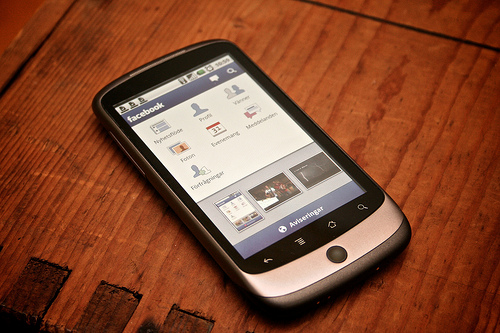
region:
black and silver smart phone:
[87, 30, 412, 317]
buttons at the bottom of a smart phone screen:
[252, 191, 378, 267]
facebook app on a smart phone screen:
[110, 44, 339, 171]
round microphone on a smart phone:
[322, 240, 353, 270]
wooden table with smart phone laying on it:
[10, 3, 492, 325]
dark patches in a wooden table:
[3, 248, 217, 327]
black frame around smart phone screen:
[98, 35, 388, 275]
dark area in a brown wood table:
[12, 0, 116, 99]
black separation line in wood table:
[292, 0, 494, 58]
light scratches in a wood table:
[23, 156, 165, 258]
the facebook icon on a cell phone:
[123, 97, 168, 132]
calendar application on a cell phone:
[204, 115, 239, 155]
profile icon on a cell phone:
[185, 92, 214, 128]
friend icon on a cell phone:
[218, 77, 245, 102]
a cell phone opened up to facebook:
[88, 31, 461, 323]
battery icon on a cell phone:
[193, 67, 214, 80]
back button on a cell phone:
[253, 251, 284, 276]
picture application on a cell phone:
[248, 163, 300, 215]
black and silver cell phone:
[76, 53, 441, 316]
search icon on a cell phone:
[225, 58, 241, 80]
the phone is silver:
[79, 30, 450, 318]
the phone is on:
[92, 5, 420, 295]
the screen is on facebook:
[98, 42, 355, 225]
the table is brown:
[346, 33, 468, 295]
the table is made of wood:
[370, 32, 470, 305]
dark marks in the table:
[5, 255, 218, 327]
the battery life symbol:
[190, 62, 210, 79]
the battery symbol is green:
[190, 62, 212, 78]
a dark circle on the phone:
[314, 238, 366, 302]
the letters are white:
[117, 99, 172, 136]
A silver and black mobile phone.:
[90, 30, 417, 325]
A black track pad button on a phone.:
[325, 243, 349, 265]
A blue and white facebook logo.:
[120, 97, 170, 124]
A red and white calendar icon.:
[202, 120, 228, 140]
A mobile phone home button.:
[322, 214, 344, 234]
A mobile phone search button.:
[354, 200, 371, 213]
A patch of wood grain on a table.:
[22, 162, 124, 257]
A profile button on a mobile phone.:
[187, 100, 209, 120]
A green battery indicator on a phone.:
[195, 66, 207, 78]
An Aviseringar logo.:
[271, 203, 330, 233]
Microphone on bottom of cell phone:
[327, 244, 347, 264]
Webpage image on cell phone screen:
[124, 48, 365, 265]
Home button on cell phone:
[327, 217, 339, 230]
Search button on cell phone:
[357, 200, 370, 213]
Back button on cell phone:
[262, 257, 273, 267]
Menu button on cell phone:
[295, 236, 305, 245]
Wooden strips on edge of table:
[7, 255, 210, 330]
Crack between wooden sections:
[313, 0, 497, 58]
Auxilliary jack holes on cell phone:
[310, 289, 336, 305]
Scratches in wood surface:
[32, 170, 139, 250]